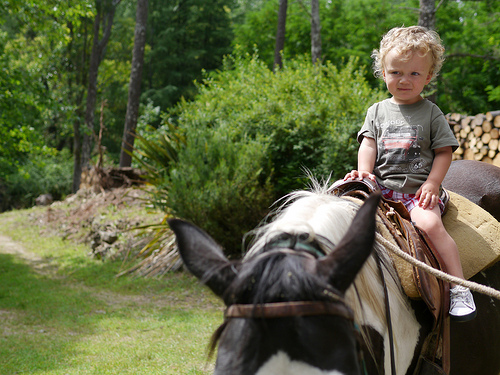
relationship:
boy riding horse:
[343, 25, 478, 322] [162, 158, 498, 373]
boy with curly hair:
[343, 25, 478, 322] [372, 24, 446, 94]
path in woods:
[2, 222, 212, 343] [22, 10, 303, 185]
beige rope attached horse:
[372, 227, 499, 302] [162, 158, 498, 373]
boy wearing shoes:
[343, 25, 478, 322] [445, 283, 476, 322]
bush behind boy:
[128, 47, 387, 257] [343, 25, 478, 322]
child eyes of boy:
[392, 71, 400, 75] [343, 25, 478, 322]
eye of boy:
[408, 65, 420, 76] [343, 25, 478, 322]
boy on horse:
[343, 25, 478, 322] [162, 158, 498, 373]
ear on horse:
[332, 191, 389, 288] [162, 158, 498, 373]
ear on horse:
[172, 211, 233, 296] [162, 158, 498, 373]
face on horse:
[222, 320, 346, 372] [162, 122, 499, 374]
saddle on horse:
[324, 170, 488, 331] [114, 147, 474, 373]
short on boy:
[365, 177, 444, 212] [343, 25, 478, 322]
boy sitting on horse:
[343, 25, 478, 322] [342, 21, 474, 319]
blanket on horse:
[428, 188, 496, 302] [162, 158, 498, 373]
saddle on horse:
[325, 176, 450, 374] [162, 158, 498, 373]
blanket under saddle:
[428, 188, 496, 302] [325, 176, 450, 374]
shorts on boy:
[375, 182, 447, 209] [343, 25, 478, 322]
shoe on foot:
[448, 282, 473, 317] [443, 282, 474, 315]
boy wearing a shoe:
[343, 25, 478, 322] [448, 282, 473, 317]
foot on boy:
[443, 282, 474, 315] [343, 25, 478, 322]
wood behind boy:
[441, 110, 498, 165] [343, 25, 478, 322]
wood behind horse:
[441, 110, 498, 165] [162, 158, 498, 373]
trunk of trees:
[81, 158, 138, 191] [1, 10, 224, 163]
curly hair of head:
[369, 23, 447, 81] [370, 22, 442, 102]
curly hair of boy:
[369, 23, 447, 81] [343, 25, 478, 322]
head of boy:
[370, 22, 442, 102] [343, 25, 478, 322]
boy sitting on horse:
[331, 19, 482, 332] [162, 158, 498, 373]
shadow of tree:
[15, 240, 130, 372] [51, 10, 148, 145]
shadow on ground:
[15, 240, 130, 372] [2, 184, 262, 373]